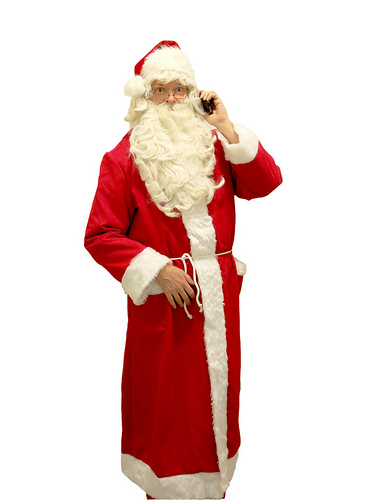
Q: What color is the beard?
A: White.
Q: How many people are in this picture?
A: One.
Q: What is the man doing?
A: Talking on the phone.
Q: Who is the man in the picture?
A: Santa Claus.